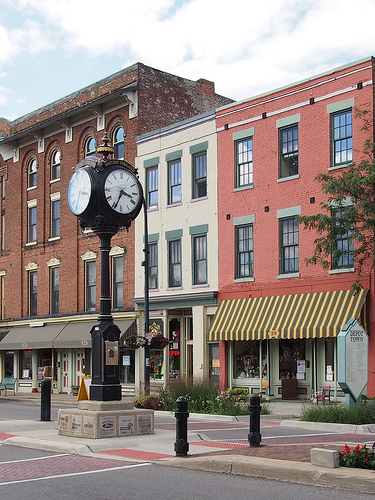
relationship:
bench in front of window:
[0, 377, 18, 398] [18, 348, 33, 381]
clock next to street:
[66, 130, 143, 403] [1, 397, 374, 500]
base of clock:
[55, 399, 156, 437] [66, 130, 143, 403]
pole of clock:
[90, 225, 121, 400] [66, 130, 143, 403]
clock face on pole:
[103, 168, 140, 215] [90, 225, 121, 400]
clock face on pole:
[68, 169, 92, 216] [90, 225, 121, 400]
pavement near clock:
[1, 419, 374, 492] [66, 130, 143, 403]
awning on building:
[207, 287, 370, 343] [215, 55, 374, 399]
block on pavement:
[310, 447, 338, 468] [1, 419, 374, 492]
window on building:
[276, 114, 303, 184] [215, 55, 374, 399]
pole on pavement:
[174, 396, 189, 457] [1, 419, 374, 492]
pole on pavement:
[249, 393, 261, 447] [1, 419, 374, 492]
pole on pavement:
[40, 380, 52, 424] [1, 419, 374, 492]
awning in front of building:
[207, 287, 370, 343] [215, 55, 374, 399]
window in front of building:
[276, 114, 303, 184] [215, 55, 374, 399]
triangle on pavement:
[75, 377, 90, 402] [1, 419, 374, 492]